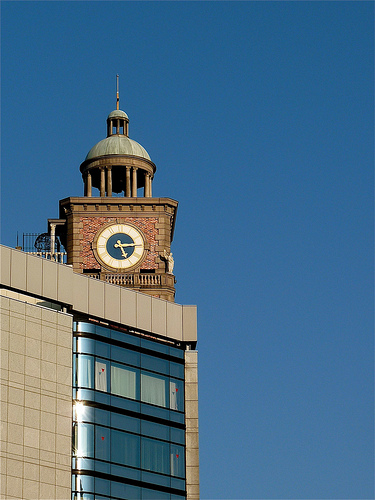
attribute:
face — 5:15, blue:
[96, 225, 146, 270]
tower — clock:
[47, 74, 177, 313]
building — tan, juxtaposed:
[4, 71, 209, 496]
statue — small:
[162, 248, 181, 281]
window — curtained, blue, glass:
[110, 362, 140, 400]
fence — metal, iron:
[13, 230, 71, 252]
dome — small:
[100, 109, 136, 121]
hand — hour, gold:
[114, 239, 130, 262]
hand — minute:
[112, 238, 146, 252]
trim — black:
[69, 327, 191, 369]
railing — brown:
[76, 267, 179, 293]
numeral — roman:
[114, 220, 128, 235]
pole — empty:
[110, 66, 127, 109]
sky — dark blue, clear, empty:
[3, 5, 374, 500]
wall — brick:
[2, 293, 78, 500]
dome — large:
[79, 135, 168, 193]